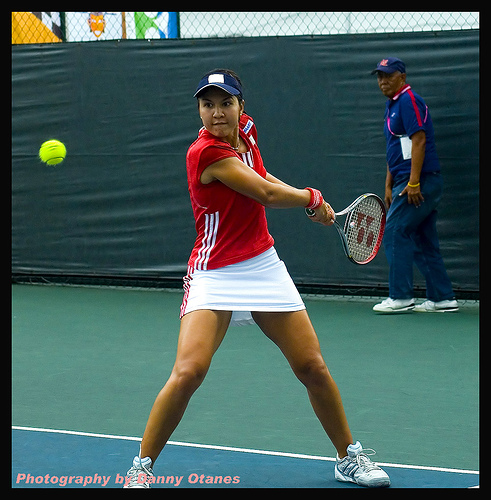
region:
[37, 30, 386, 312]
a tennis player hitting a ball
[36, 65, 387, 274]
a woman hitting a tennis ball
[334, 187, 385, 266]
a red and silver tennis racket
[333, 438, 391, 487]
a blue and white tennis shoe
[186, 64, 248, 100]
a blue and white visor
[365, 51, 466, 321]
a linesman at a tennis match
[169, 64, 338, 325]
a woman wearing a red and white tennis outfit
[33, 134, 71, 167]
a yellow tennis ball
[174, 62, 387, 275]
a woman hitting a backhand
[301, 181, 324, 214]
a red and white wrist band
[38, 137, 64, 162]
a tennis ball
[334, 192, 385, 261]
A black and red tennis racquet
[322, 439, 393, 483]
White and blue tennis shoes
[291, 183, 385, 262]
holding a tennis racquet with both hands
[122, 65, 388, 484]
a woman playing tennis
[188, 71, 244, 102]
a navy blue tennis visor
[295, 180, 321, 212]
a red tennis sweatband wristband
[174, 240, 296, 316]
an adidas white woman tennis skirt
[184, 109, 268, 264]
a red Adidas tennis woman shirt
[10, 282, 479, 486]
A Tennis court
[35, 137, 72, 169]
A neon yellow tennis ball in the air.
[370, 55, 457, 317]
A tennis coach wearing a blue uniform.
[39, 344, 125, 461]
White markings on a blue and green tennis court.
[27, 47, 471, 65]
A dark green material stretched on a fence.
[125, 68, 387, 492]
A tennis player holding a tennis racket.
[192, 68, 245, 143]
Woman wearing a blue baseball cap playing tennis.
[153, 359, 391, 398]
The strong knees of a good tennis player.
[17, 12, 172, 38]
Team logos shown in the upper left corner.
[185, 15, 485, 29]
A chain link fence surrounds a tennis court.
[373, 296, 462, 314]
White tennis shoes with a long black stripe.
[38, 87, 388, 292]
A woman playing tennis.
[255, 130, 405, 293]
A woman holding a tennis racket.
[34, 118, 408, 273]
A woman swinging at the ball.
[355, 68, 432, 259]
A man standing on the side of the court.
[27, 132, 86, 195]
A yellow ball in the air.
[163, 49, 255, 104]
the woman is wearing a sunvisor.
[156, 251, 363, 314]
The woman is wearing a white skirt.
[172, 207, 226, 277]
White lines on the side of the shirt.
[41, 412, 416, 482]
A white line on the court.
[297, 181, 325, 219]
The lady is wearing a blue wristband.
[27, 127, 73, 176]
A small tennis ball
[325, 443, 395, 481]
The bottom right shoe of the tennis player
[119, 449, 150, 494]
The bottom left shoe of the tennis player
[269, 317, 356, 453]
The right leg of the tennis player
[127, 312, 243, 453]
The left leg of the tennis player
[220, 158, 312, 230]
The right arm of the tennis player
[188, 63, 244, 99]
The cap of the tennis player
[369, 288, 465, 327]
The man's boittom shoes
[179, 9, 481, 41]
The fencing of the area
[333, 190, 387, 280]
The tennis racket of the player